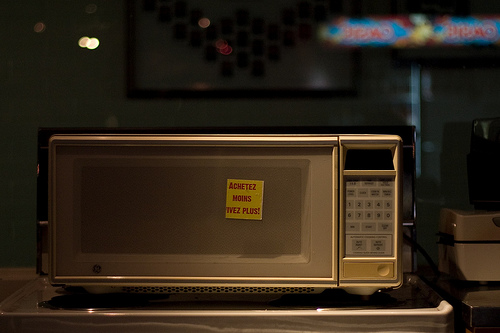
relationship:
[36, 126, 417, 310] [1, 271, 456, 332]
microwave on countertop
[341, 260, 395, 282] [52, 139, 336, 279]
button used to open microwave door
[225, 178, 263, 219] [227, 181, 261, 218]
print with red lettering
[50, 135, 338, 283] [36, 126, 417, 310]
door of microwave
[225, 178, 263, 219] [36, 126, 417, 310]
print on microwave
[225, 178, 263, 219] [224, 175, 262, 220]
print with print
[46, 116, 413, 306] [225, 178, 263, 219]
microwave with print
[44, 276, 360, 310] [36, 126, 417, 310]
underside of microwave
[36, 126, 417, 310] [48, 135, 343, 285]
microwave has door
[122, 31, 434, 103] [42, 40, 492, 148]
picture on wall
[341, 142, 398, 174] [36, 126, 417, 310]
screen in microwave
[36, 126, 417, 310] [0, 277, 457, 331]
microwave sitting on countertop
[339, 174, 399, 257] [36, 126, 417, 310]
control panel on microwave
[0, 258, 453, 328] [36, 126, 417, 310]
counter under microwave